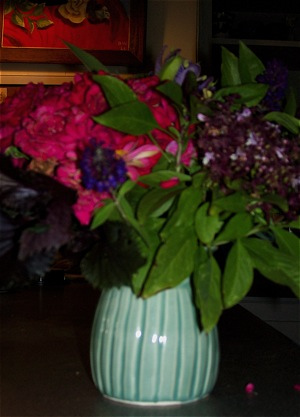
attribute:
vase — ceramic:
[109, 288, 199, 409]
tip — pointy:
[139, 293, 150, 300]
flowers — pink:
[6, 73, 198, 229]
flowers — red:
[21, 74, 186, 221]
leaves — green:
[73, 152, 283, 325]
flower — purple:
[201, 88, 291, 199]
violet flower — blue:
[76, 139, 126, 190]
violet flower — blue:
[195, 104, 299, 193]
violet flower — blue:
[174, 63, 208, 87]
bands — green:
[88, 281, 220, 405]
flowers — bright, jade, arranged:
[3, 40, 292, 304]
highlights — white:
[106, 309, 193, 375]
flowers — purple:
[6, 52, 299, 235]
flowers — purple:
[208, 105, 291, 201]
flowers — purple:
[259, 60, 288, 103]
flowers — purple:
[85, 144, 121, 185]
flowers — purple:
[11, 77, 171, 191]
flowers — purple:
[11, 70, 292, 215]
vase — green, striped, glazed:
[91, 273, 219, 409]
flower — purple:
[76, 139, 125, 189]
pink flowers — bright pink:
[0, 67, 198, 225]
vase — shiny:
[102, 295, 197, 385]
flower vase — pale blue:
[92, 282, 221, 403]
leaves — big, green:
[126, 167, 297, 332]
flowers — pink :
[13, 62, 243, 258]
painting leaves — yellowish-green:
[11, 17, 55, 31]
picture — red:
[0, 0, 201, 90]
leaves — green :
[59, 38, 296, 330]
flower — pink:
[3, 82, 199, 188]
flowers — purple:
[197, 90, 299, 223]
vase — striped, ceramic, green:
[87, 282, 221, 405]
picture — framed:
[1, 1, 155, 87]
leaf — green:
[191, 246, 225, 328]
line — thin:
[168, 290, 187, 405]